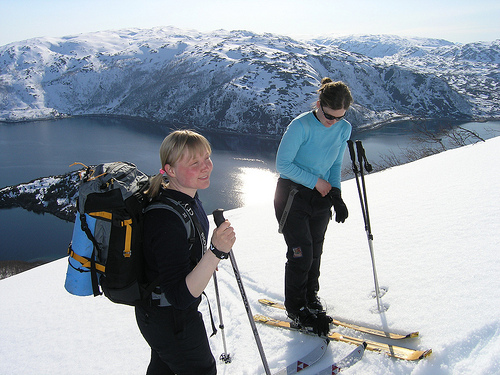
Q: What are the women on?
A: Skis.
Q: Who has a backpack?
A: The lady.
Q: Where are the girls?
A: In the snow.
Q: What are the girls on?
A: A mountain.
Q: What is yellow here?
A: The skis.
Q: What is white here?
A: The snow.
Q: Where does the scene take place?
A: On a snowy mountain.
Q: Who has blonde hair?
A: Woman on left.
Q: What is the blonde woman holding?
A: Ski poles.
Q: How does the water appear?
A: Dark and calm.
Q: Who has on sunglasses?
A: Woman in blue.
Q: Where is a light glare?
A: On the water.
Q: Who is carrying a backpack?
A: Blonde woman.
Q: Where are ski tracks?
A: On the snow.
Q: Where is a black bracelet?
A: Around blonde's wrist.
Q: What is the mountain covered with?
A: Snow.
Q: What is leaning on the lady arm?
A: Ski poles.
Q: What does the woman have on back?
A: Backpack.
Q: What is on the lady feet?
A: Skis.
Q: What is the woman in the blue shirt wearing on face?
A: Sunglasses.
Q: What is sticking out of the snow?
A: Ski poles.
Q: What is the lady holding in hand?
A: Ski pole.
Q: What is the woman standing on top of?
A: Skis.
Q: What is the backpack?
A: On woman back.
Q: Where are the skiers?
A: On a mountain.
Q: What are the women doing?
A: Skiing.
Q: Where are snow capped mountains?
A: Across the water.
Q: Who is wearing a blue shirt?
A: Woman on right.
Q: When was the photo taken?
A: Daytime.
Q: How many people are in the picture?
A: Two.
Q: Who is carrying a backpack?
A: Blond woman.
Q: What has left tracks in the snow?
A: Skis.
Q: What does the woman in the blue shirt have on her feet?
A: Skis.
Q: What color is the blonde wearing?
A: Black.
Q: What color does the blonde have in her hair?
A: Pink.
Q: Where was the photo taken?
A: On a ski trail overlooking a lake.